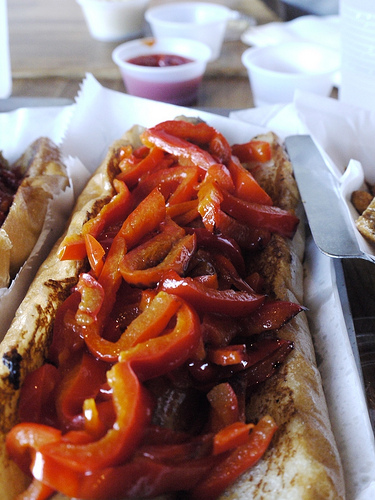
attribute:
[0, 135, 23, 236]
steak — Philly steak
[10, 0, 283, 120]
table — brown, wood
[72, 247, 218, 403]
red pepper — large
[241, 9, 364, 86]
napkin — white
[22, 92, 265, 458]
peppers — sauteed, red, sweet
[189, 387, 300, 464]
pepper — red, large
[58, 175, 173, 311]
pepper — large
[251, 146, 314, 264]
bread — toasted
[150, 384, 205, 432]
sausage — link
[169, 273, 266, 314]
red pepper — large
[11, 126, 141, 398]
bun — toasted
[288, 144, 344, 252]
edge — metal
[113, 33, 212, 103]
cup — small, Ketchup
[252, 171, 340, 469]
bun — toasted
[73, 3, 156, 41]
cup — condiment cup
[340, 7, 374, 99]
container — clear, plastic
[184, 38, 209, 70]
cup — small, clear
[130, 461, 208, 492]
pepper — red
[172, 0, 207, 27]
something — white